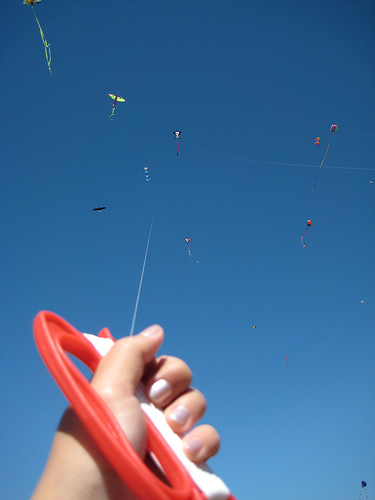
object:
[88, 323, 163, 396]
thumb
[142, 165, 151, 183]
blue kite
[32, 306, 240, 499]
holder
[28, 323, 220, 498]
boy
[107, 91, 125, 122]
kite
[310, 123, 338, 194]
kite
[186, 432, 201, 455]
polish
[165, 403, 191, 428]
nails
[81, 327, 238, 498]
piece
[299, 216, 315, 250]
kite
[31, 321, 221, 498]
hand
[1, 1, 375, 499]
sky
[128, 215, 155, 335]
string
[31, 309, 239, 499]
handle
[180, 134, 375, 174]
thread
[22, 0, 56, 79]
kite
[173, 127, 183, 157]
kite